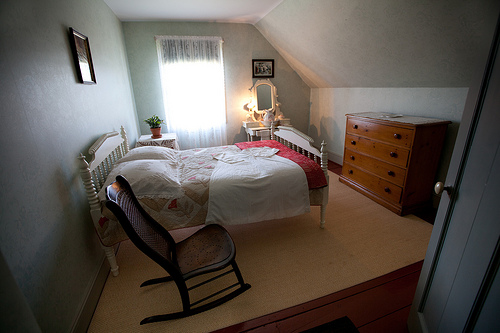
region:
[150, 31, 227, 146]
White shear bedroom curtains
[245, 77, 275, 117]
Mirror attached to wall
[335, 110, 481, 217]
Tan dresser against wall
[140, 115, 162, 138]
Flower pot on table next to the bed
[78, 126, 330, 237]
Bed against the wall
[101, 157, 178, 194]
Pillow on right side of bed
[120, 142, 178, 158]
Pillow on left side of bed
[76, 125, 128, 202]
Wood headboard of bed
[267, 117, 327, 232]
Wood footboard of bed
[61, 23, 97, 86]
Picture hanging on wall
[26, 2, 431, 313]
an oddly shaped room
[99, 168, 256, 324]
a dark rocking chair with no arms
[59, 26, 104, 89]
light reflecting off of framed object on wall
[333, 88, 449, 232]
wooden chest of drawers near a wall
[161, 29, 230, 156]
sheer curtain covering window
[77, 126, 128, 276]
white wooden headboard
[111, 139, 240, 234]
quilt on bed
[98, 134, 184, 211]
large pillows on bed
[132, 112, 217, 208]
table beside bed with a plant on it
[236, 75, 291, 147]
mirror and table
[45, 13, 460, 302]
A bedroom is pictured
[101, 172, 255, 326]
A rocking chair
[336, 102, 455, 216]
This is a dresser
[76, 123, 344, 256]
A bed is in the center of the room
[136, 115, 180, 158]
A stand with a plant on it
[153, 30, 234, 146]
A window is at the end of the room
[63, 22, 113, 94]
A framed picture is hanging on the wall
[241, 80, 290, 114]
This is a mirror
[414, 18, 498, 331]
This is the door to the room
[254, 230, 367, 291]
The floor is carpeted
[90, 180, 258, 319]
A wooden rocking chair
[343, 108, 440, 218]
A brown wooden dresser.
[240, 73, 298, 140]
A white vanity table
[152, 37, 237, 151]
Curtains hanging on a window.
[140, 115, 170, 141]
A potted indoor plant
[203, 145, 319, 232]
A white nightgown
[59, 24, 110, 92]
A picture hanging on a wall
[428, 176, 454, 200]
A white doorknob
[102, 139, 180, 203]
Two pillows on a bed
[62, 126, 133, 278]
A white headboard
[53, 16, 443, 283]
a very small attic-type bedroom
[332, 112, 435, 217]
a wooden dresser with four drawers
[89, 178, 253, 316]
a dark wood rocking chair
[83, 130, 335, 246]
a white wood framed double bed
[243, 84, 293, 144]
a small white vanity table with a mirror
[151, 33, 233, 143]
white lace shear curtains covering a small window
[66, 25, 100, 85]
a wooden framed picture on the wall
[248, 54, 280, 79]
a very small framed picture on the wall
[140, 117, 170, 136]
a small plant in a pot on a table near the window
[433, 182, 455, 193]
a metal door knob on the door to the bedroom